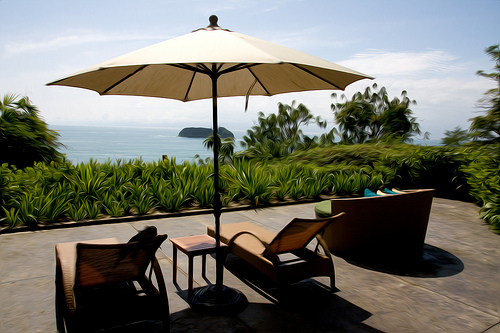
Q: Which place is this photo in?
A: It is at the porch.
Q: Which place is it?
A: It is a porch.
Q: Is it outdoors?
A: Yes, it is outdoors.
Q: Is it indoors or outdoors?
A: It is outdoors.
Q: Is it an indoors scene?
A: No, it is outdoors.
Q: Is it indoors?
A: No, it is outdoors.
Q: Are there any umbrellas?
A: Yes, there is an umbrella.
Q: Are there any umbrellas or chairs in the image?
A: Yes, there is an umbrella.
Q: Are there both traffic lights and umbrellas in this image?
A: No, there is an umbrella but no traffic lights.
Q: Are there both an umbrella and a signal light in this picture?
A: No, there is an umbrella but no traffic lights.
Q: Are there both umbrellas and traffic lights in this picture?
A: No, there is an umbrella but no traffic lights.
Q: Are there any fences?
A: No, there are no fences.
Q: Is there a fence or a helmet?
A: No, there are no fences or helmets.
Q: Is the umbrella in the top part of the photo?
A: Yes, the umbrella is in the top of the image.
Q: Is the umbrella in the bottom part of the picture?
A: No, the umbrella is in the top of the image.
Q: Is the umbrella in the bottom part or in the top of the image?
A: The umbrella is in the top of the image.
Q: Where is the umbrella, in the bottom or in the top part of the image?
A: The umbrella is in the top of the image.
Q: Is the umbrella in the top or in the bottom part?
A: The umbrella is in the top of the image.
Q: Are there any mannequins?
A: No, there are no mannequins.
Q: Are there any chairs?
A: Yes, there is a chair.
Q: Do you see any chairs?
A: Yes, there is a chair.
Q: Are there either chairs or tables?
A: Yes, there is a chair.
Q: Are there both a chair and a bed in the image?
A: No, there is a chair but no beds.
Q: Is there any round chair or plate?
A: Yes, there is a round chair.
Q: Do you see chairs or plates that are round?
A: Yes, the chair is round.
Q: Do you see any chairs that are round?
A: Yes, there is a round chair.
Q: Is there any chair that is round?
A: Yes, there is a chair that is round.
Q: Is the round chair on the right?
A: Yes, the chair is on the right of the image.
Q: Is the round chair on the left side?
A: No, the chair is on the right of the image.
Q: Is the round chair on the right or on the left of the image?
A: The chair is on the right of the image.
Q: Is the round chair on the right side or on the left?
A: The chair is on the right of the image.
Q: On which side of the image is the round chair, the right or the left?
A: The chair is on the right of the image.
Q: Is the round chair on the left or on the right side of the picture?
A: The chair is on the right of the image.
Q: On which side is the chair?
A: The chair is on the right of the image.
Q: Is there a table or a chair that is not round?
A: No, there is a chair but it is round.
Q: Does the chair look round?
A: Yes, the chair is round.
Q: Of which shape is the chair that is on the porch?
A: The chair is round.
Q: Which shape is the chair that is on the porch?
A: The chair is round.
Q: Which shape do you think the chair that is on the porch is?
A: The chair is round.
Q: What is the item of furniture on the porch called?
A: The piece of furniture is a chair.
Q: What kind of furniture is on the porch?
A: The piece of furniture is a chair.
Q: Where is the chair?
A: The chair is on the porch.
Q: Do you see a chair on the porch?
A: Yes, there is a chair on the porch.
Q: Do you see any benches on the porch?
A: No, there is a chair on the porch.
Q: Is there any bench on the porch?
A: No, there is a chair on the porch.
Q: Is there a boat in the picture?
A: No, there are no boats.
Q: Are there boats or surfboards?
A: No, there are no boats or surfboards.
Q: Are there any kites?
A: No, there are no kites.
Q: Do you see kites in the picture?
A: No, there are no kites.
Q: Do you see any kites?
A: No, there are no kites.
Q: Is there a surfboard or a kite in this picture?
A: No, there are no kites or surfboards.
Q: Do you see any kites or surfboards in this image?
A: No, there are no kites or surfboards.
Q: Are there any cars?
A: No, there are no cars.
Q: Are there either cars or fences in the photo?
A: No, there are no cars or fences.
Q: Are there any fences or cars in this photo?
A: No, there are no cars or fences.